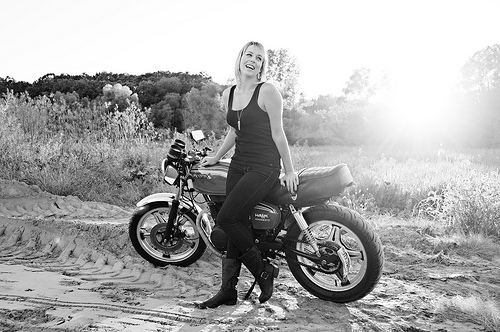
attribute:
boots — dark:
[242, 260, 278, 294]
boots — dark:
[205, 258, 237, 310]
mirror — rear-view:
[161, 162, 180, 187]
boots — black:
[166, 212, 294, 321]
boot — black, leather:
[220, 238, 278, 310]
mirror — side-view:
[158, 156, 185, 189]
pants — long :
[216, 164, 276, 251]